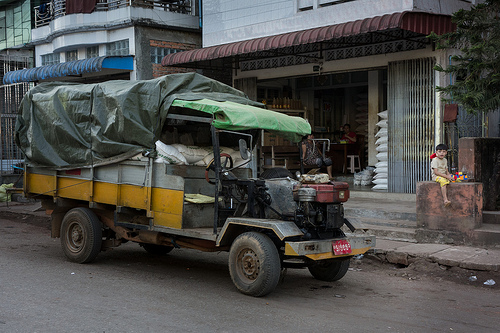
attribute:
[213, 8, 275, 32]
wall — white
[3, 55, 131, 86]
covering — blue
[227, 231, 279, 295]
tire — dirty, muddy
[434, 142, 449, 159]
girl — light skinned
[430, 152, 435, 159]
hairband — red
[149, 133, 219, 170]
truck — loaded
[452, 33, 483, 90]
leaves — green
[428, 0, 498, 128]
tree — green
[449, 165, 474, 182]
toy — colored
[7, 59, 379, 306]
truck — orange, old, packed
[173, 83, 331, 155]
canopy — green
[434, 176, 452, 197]
pants — yellow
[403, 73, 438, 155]
shutter — metal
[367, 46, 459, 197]
bonnet — uncovered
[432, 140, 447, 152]
hair — dark